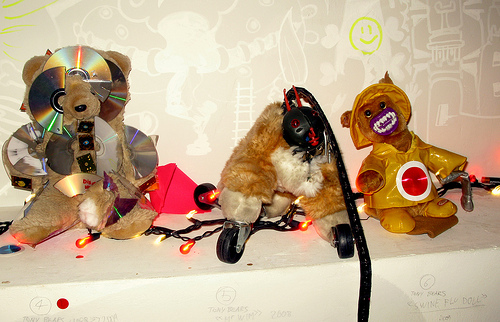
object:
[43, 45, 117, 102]
cd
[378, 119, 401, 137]
lips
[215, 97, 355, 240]
stuffed animal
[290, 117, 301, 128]
mask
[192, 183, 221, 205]
light bulb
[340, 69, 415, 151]
hat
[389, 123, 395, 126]
teeth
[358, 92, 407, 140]
head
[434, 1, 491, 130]
wallpaper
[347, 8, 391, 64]
happy face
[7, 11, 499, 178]
wall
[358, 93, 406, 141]
face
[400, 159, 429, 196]
target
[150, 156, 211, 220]
paper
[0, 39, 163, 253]
toys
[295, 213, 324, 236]
light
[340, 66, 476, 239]
animal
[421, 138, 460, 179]
left arm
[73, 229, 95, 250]
lights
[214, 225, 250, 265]
wheels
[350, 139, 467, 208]
raincoat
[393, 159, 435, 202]
circle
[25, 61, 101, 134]
cds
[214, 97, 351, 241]
plushie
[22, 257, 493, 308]
shelf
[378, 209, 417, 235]
rain shoe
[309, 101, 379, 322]
tubing